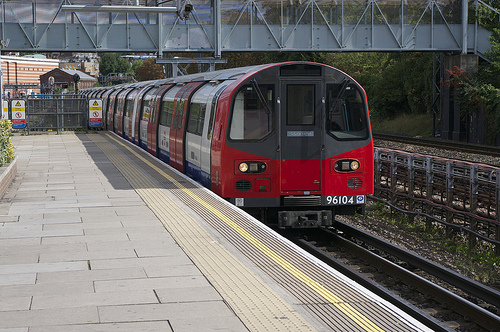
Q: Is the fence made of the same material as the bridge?
A: Yes, both the fence and the bridge are made of metal.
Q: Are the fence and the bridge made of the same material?
A: Yes, both the fence and the bridge are made of metal.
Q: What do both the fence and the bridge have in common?
A: The material, both the fence and the bridge are metallic.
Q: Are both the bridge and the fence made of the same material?
A: Yes, both the bridge and the fence are made of metal.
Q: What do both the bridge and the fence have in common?
A: The material, both the bridge and the fence are metallic.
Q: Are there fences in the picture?
A: Yes, there is a fence.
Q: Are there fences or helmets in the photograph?
A: Yes, there is a fence.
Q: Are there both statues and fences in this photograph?
A: No, there is a fence but no statues.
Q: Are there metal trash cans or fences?
A: Yes, there is a metal fence.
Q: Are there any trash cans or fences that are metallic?
A: Yes, the fence is metallic.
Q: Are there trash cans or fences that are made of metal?
A: Yes, the fence is made of metal.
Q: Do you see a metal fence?
A: Yes, there is a metal fence.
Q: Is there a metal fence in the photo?
A: Yes, there is a metal fence.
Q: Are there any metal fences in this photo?
A: Yes, there is a metal fence.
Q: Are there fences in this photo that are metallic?
A: Yes, there is a fence that is metallic.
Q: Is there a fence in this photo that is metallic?
A: Yes, there is a fence that is metallic.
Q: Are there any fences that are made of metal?
A: Yes, there is a fence that is made of metal.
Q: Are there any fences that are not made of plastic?
A: Yes, there is a fence that is made of metal.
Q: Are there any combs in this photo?
A: No, there are no combs.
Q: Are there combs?
A: No, there are no combs.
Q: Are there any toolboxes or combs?
A: No, there are no combs or toolboxes.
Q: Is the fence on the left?
A: Yes, the fence is on the left of the image.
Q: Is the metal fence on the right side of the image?
A: No, the fence is on the left of the image.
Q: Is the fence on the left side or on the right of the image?
A: The fence is on the left of the image.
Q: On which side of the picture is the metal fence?
A: The fence is on the left of the image.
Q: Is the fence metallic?
A: Yes, the fence is metallic.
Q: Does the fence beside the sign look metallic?
A: Yes, the fence is metallic.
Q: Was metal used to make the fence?
A: Yes, the fence is made of metal.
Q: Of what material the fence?
A: The fence is made of metal.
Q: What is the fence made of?
A: The fence is made of metal.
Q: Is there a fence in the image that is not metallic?
A: No, there is a fence but it is metallic.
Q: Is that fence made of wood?
A: No, the fence is made of metal.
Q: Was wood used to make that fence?
A: No, the fence is made of metal.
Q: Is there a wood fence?
A: No, there is a fence but it is made of metal.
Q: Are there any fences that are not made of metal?
A: No, there is a fence but it is made of metal.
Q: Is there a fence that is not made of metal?
A: No, there is a fence but it is made of metal.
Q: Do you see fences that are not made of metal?
A: No, there is a fence but it is made of metal.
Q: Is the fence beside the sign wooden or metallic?
A: The fence is metallic.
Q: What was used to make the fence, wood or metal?
A: The fence is made of metal.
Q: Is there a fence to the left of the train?
A: Yes, there is a fence to the left of the train.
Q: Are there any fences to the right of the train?
A: No, the fence is to the left of the train.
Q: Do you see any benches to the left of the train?
A: No, there is a fence to the left of the train.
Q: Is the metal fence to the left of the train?
A: Yes, the fence is to the left of the train.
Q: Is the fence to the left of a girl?
A: No, the fence is to the left of the train.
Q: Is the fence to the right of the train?
A: No, the fence is to the left of the train.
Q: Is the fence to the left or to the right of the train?
A: The fence is to the left of the train.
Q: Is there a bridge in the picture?
A: Yes, there is a bridge.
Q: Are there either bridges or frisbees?
A: Yes, there is a bridge.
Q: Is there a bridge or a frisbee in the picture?
A: Yes, there is a bridge.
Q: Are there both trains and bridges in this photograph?
A: Yes, there are both a bridge and a train.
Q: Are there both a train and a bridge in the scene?
A: Yes, there are both a bridge and a train.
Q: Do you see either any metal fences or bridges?
A: Yes, there is a metal bridge.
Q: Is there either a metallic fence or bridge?
A: Yes, there is a metal bridge.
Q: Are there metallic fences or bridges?
A: Yes, there is a metal bridge.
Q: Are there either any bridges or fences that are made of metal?
A: Yes, the bridge is made of metal.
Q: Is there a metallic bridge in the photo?
A: Yes, there is a metal bridge.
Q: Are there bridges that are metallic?
A: Yes, there is a bridge that is metallic.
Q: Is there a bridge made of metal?
A: Yes, there is a bridge that is made of metal.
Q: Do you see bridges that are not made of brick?
A: Yes, there is a bridge that is made of metal.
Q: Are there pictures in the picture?
A: No, there are no pictures.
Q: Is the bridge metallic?
A: Yes, the bridge is metallic.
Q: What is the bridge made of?
A: The bridge is made of metal.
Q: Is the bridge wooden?
A: No, the bridge is metallic.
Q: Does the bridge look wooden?
A: No, the bridge is metallic.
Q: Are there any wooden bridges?
A: No, there is a bridge but it is metallic.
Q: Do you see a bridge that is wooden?
A: No, there is a bridge but it is metallic.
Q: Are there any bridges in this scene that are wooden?
A: No, there is a bridge but it is metallic.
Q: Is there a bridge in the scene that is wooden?
A: No, there is a bridge but it is metallic.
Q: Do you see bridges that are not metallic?
A: No, there is a bridge but it is metallic.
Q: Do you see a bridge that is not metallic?
A: No, there is a bridge but it is metallic.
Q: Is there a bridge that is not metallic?
A: No, there is a bridge but it is metallic.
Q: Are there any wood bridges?
A: No, there is a bridge but it is made of metal.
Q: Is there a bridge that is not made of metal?
A: No, there is a bridge but it is made of metal.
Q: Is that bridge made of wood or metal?
A: The bridge is made of metal.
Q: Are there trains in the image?
A: Yes, there is a train.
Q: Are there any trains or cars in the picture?
A: Yes, there is a train.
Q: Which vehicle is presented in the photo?
A: The vehicle is a train.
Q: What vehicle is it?
A: The vehicle is a train.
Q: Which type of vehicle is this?
A: This is a train.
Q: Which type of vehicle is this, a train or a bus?
A: This is a train.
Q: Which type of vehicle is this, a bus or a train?
A: This is a train.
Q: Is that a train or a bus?
A: That is a train.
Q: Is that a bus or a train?
A: That is a train.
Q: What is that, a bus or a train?
A: That is a train.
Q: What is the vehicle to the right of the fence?
A: The vehicle is a train.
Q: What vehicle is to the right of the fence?
A: The vehicle is a train.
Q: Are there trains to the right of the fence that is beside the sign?
A: Yes, there is a train to the right of the fence.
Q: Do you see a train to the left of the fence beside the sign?
A: No, the train is to the right of the fence.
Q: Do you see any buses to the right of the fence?
A: No, there is a train to the right of the fence.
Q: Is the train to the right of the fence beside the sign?
A: Yes, the train is to the right of the fence.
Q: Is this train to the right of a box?
A: No, the train is to the right of the fence.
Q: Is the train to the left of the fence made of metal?
A: No, the train is to the right of the fence.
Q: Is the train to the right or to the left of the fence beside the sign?
A: The train is to the right of the fence.